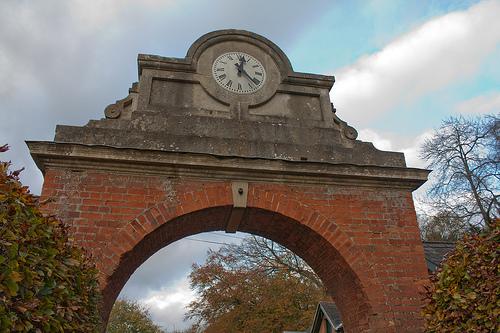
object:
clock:
[211, 51, 266, 94]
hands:
[238, 56, 244, 77]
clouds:
[342, 1, 497, 112]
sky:
[1, 0, 499, 332]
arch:
[91, 185, 396, 333]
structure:
[23, 28, 432, 333]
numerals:
[214, 52, 265, 90]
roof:
[305, 302, 342, 331]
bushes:
[1, 166, 97, 332]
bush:
[421, 234, 499, 333]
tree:
[422, 112, 498, 242]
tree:
[184, 235, 333, 332]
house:
[309, 235, 460, 333]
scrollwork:
[103, 103, 123, 119]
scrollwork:
[344, 125, 358, 139]